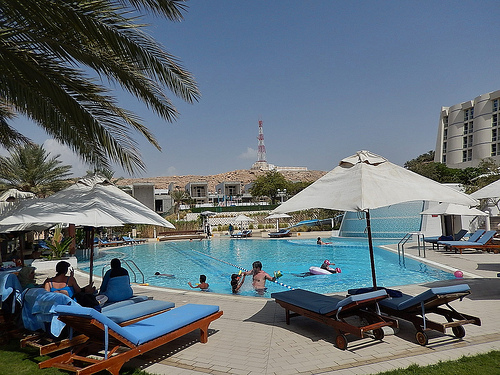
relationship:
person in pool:
[241, 261, 283, 293] [79, 234, 469, 301]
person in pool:
[230, 274, 245, 295] [79, 234, 469, 301]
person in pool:
[185, 275, 212, 293] [79, 234, 469, 301]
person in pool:
[290, 260, 341, 275] [79, 234, 469, 301]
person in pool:
[155, 270, 179, 282] [79, 234, 469, 301]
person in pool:
[316, 238, 334, 249] [79, 234, 469, 301]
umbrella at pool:
[270, 152, 478, 339] [79, 234, 469, 301]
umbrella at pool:
[0, 177, 175, 297] [79, 234, 469, 301]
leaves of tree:
[0, 0, 201, 179] [0, 0, 203, 176]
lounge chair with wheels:
[272, 289, 390, 349] [333, 329, 387, 349]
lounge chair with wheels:
[348, 284, 482, 345] [418, 328, 470, 348]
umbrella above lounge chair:
[270, 152, 478, 339] [272, 289, 390, 349]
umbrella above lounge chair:
[270, 152, 478, 339] [348, 284, 482, 345]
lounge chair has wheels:
[272, 289, 390, 349] [333, 329, 387, 349]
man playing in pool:
[241, 261, 283, 293] [79, 234, 469, 301]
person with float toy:
[290, 260, 341, 275] [309, 265, 336, 278]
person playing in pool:
[155, 270, 179, 282] [79, 234, 469, 301]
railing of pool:
[398, 233, 426, 269] [79, 234, 469, 301]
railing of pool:
[102, 259, 146, 285] [79, 234, 469, 301]